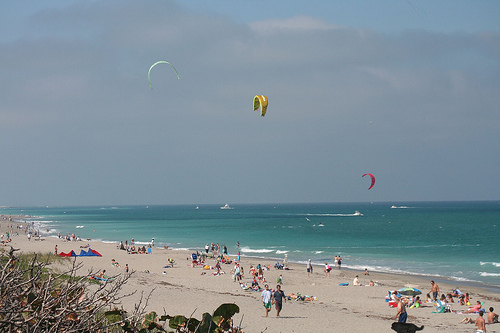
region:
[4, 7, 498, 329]
Beach on a sunny day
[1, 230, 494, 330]
Lots of people in beack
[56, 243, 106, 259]
Blue and red tents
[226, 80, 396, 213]
Kites flying in the sky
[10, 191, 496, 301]
waters of sea are green and blue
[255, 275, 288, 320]
Two person walking on the sand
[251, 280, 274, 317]
Person with a white shirt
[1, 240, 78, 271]
Green patch on sand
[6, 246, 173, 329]
Branches without leaves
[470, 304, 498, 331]
Two man without tops on right corner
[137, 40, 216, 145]
green parasail in the sky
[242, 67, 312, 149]
yellow parasail in the sky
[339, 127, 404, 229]
red parasail in the sky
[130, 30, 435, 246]
three parasails in the sky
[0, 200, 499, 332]
people on the beach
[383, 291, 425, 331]
man with dog on the beach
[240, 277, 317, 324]
two people walking along the beach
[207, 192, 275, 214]
boat sailing on the sea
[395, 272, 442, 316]
umbrella on the beach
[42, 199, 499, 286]
blue sea water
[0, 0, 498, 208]
the sky is blue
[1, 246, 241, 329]
a scrubby brush is in the foreground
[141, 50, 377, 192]
three kites fly high in the sky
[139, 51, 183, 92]
a white kite is in the sky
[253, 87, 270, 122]
a yellow kite is in the sky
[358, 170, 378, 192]
a red kite is in the sky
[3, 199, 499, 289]
the ocean is blue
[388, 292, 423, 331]
a man in blue shorts is walking a dog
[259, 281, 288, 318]
two men walk together towards the man walking a black dog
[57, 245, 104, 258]
a red and blue kite is lying on the beach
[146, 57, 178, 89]
light green curved large kite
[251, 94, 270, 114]
yellow curved large kite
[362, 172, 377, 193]
red curved large kite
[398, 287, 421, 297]
blue and green beach umbrella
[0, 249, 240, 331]
bush with a few leaves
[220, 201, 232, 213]
white boat floating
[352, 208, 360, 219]
white boat driving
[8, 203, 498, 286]
blue green ocean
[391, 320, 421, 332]
large black dog walking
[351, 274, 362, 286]
person sitting on beach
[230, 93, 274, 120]
yellow kite in the sky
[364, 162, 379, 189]
red kite in the sky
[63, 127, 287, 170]
the sky is cloudy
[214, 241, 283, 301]
people on the beach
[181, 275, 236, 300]
the sand is brown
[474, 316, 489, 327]
the person has no shirt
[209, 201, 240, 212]
the boat is out to sea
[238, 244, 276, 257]
small waves in the sea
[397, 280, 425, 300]
the umbrella is multicolored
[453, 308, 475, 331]
person is laying on the ground